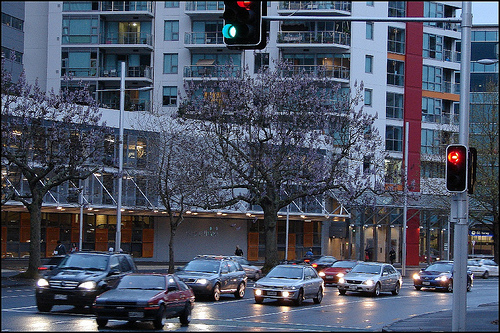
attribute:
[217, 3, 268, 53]
traffic signal — electric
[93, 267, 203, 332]
car — old, black, red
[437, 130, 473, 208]
light — black, silver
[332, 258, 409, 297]
car — silver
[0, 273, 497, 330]
surface — wet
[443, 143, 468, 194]
traffic light — bright, red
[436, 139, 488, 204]
signal — lectrical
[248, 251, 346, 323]
car — silver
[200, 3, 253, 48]
light — bright, green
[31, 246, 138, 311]
suv — black 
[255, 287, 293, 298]
headlights — yellow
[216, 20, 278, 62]
traffic light — green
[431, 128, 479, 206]
light — red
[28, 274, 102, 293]
headlights — on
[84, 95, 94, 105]
flower — purple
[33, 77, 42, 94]
flower — purple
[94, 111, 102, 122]
flower — purple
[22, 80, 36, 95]
flower — purple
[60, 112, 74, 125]
flower — purple